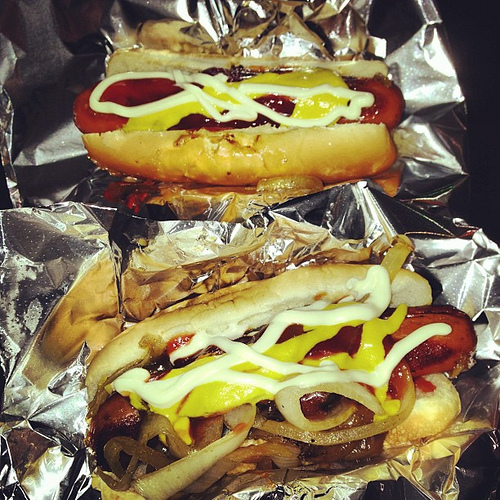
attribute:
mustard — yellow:
[185, 387, 251, 411]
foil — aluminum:
[1, 182, 483, 498]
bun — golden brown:
[81, 119, 398, 189]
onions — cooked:
[98, 372, 415, 494]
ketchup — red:
[326, 331, 347, 349]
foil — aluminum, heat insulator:
[17, 190, 490, 329]